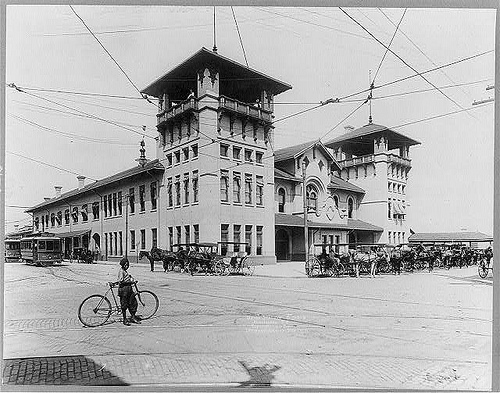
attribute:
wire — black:
[97, 49, 159, 111]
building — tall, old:
[0, 47, 420, 267]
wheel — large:
[77, 293, 116, 329]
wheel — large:
[127, 287, 160, 320]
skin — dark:
[112, 256, 132, 279]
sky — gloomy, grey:
[64, 38, 143, 133]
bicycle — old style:
[76, 285, 138, 332]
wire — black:
[64, 20, 183, 131]